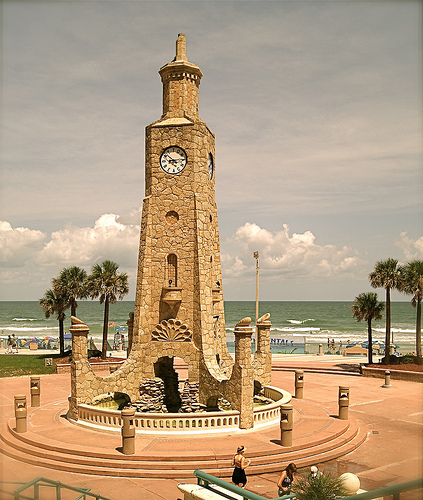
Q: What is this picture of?
A: Clock tower.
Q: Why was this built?
A: To show time.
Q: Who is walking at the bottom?
A: A woman.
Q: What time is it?
A: 2:50.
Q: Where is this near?
A: The beach.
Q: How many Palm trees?
A: 6.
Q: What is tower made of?
A: Stones.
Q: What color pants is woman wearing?
A: Black.